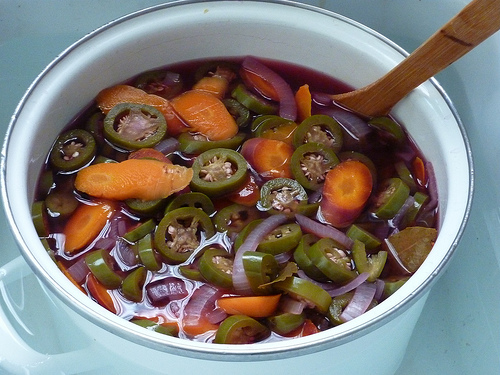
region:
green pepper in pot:
[190, 143, 240, 181]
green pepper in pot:
[114, 99, 168, 139]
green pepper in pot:
[51, 123, 96, 167]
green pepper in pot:
[152, 203, 206, 255]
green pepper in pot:
[255, 218, 302, 259]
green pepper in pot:
[315, 236, 369, 294]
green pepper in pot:
[368, 183, 402, 234]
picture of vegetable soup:
[77, 223, 318, 371]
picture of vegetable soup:
[123, 205, 239, 292]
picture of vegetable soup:
[184, 213, 453, 347]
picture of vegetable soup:
[127, 268, 389, 335]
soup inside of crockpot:
[5, 3, 474, 370]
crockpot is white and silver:
[1, 0, 476, 374]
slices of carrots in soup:
[36, 56, 438, 349]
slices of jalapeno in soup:
[30, 54, 438, 341]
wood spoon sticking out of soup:
[332, 1, 499, 123]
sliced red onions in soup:
[31, 53, 441, 348]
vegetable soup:
[35, 55, 440, 347]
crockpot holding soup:
[2, 2, 472, 372]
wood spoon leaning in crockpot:
[325, 2, 499, 121]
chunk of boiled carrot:
[322, 158, 373, 233]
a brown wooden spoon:
[325, 0, 499, 115]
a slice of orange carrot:
[172, 90, 232, 138]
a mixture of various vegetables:
[28, 53, 430, 342]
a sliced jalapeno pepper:
[191, 146, 245, 189]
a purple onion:
[293, 213, 351, 249]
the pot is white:
[4, 1, 474, 373]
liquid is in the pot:
[31, 55, 442, 343]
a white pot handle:
[1, 254, 98, 372]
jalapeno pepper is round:
[155, 206, 215, 266]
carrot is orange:
[321, 158, 372, 211]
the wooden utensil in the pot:
[329, 0, 499, 120]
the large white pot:
[0, 0, 471, 374]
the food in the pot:
[33, 57, 438, 344]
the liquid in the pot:
[31, 55, 436, 342]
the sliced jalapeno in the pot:
[192, 147, 248, 192]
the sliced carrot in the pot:
[75, 158, 195, 200]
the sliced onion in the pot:
[231, 212, 286, 293]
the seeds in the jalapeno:
[201, 155, 234, 182]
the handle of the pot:
[0, 250, 90, 372]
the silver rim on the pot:
[0, 0, 472, 361]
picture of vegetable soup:
[188, 339, 190, 340]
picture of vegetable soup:
[171, 300, 188, 305]